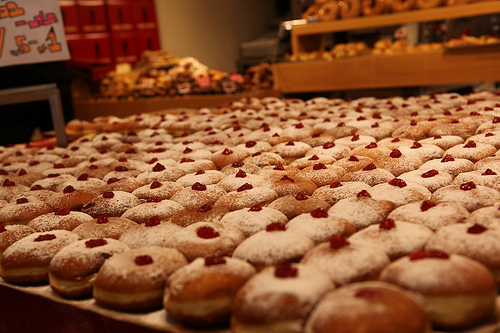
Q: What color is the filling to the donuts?
A: Red.